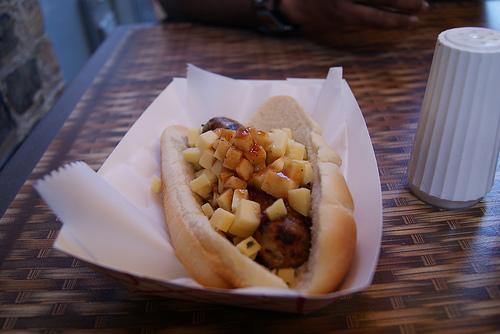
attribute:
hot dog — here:
[203, 114, 312, 266]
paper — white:
[33, 62, 348, 287]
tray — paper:
[51, 76, 385, 314]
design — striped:
[76, 257, 345, 315]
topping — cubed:
[185, 128, 313, 256]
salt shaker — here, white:
[403, 25, 499, 212]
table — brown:
[1, 26, 497, 334]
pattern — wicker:
[2, 28, 499, 334]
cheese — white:
[235, 235, 260, 259]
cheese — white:
[187, 128, 317, 258]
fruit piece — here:
[198, 132, 219, 149]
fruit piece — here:
[230, 198, 263, 238]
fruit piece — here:
[260, 171, 297, 200]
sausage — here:
[200, 115, 313, 269]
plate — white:
[50, 78, 386, 315]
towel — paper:
[30, 62, 357, 296]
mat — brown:
[1, 23, 499, 331]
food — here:
[159, 94, 358, 300]